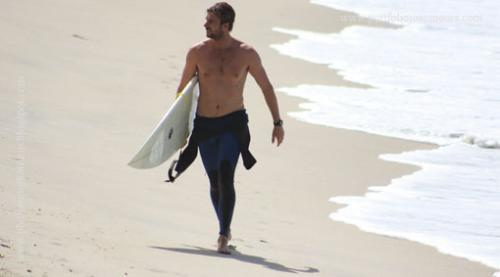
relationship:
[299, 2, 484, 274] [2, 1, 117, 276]
shorline on beach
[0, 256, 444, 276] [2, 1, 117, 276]
sand on beach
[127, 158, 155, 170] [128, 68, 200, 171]
tip of surfboard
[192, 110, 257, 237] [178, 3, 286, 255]
wetsuit on man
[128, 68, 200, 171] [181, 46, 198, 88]
surfboard under arm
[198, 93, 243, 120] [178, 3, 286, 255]
stomach on man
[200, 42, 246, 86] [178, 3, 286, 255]
chest on man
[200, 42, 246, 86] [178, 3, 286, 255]
chest of man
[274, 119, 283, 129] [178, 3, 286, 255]
watch on man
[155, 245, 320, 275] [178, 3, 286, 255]
shadow of man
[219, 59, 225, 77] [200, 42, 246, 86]
hair on chest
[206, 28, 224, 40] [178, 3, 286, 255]
beard on man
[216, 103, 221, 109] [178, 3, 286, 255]
belly-button on man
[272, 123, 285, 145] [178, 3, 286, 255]
hand of man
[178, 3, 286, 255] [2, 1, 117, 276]
man on beach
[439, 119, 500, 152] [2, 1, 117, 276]
waves on beach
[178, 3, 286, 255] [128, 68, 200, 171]
man carrying a surfboard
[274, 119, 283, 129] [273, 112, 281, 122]
watch on wrist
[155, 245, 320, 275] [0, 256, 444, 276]
shadow on sand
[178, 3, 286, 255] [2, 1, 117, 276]
man walking on beach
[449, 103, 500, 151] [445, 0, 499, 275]
foam on water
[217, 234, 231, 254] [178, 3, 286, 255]
feet of man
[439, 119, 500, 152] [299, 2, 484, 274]
waves at shoreline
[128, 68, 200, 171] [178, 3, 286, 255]
surfboard of man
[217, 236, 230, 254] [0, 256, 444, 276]
feet in sand